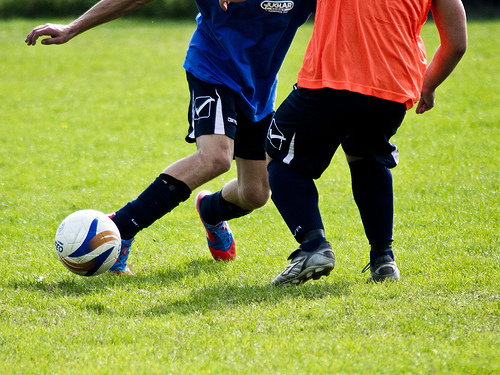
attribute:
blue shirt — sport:
[186, 5, 304, 117]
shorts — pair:
[185, 72, 274, 162]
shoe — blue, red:
[190, 188, 240, 263]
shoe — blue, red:
[99, 206, 139, 282]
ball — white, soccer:
[42, 193, 137, 293]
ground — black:
[397, 155, 428, 197]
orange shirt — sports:
[297, 0, 429, 106]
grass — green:
[7, 21, 496, 373]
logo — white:
[260, 0, 295, 17]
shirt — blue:
[187, 0, 299, 112]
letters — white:
[261, 0, 290, 15]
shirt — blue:
[183, 0, 317, 122]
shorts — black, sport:
[255, 90, 400, 180]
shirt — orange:
[291, 0, 426, 105]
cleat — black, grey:
[257, 234, 362, 306]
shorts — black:
[189, 87, 276, 163]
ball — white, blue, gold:
[50, 201, 126, 283]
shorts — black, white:
[181, 69, 408, 180]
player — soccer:
[61, 13, 286, 290]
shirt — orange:
[291, 0, 432, 115]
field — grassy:
[2, 15, 499, 374]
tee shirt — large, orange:
[295, 0, 432, 112]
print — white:
[188, 89, 220, 126]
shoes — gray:
[268, 235, 337, 289]